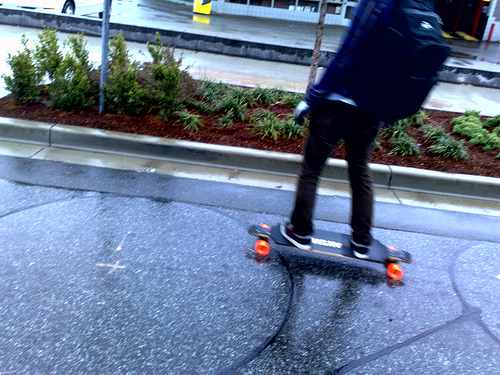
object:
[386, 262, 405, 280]
wheel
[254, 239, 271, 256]
wheel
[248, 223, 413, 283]
board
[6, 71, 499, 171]
dirt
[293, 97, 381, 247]
jeans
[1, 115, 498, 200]
curb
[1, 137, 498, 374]
road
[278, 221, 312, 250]
shoes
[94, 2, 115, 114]
pole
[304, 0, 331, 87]
pole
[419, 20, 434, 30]
logo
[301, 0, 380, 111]
blue shirt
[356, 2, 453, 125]
backpack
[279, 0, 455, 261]
man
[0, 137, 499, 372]
ground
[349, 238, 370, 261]
skate shoes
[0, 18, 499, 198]
median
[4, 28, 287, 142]
plants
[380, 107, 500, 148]
plants